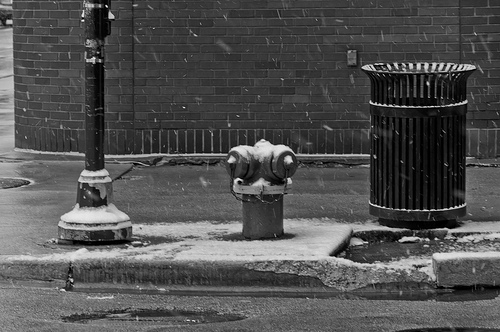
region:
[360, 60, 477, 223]
a trash can on the sidewalk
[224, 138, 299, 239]
a fire hydrant on the sidewalk near the curb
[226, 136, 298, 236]
a fire hydrant between a trash can and a pole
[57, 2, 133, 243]
a pole beside the fire hydrant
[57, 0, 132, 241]
a pole near the curb on the sidewalk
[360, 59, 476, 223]
a trash can beside a fire hydrant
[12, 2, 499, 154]
a brick wall to a building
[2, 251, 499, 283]
the curb beside the street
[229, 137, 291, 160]
snow on top of the fire hydrant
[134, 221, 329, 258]
snow on the sidewalk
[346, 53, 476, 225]
trash receptacle on the sidewalk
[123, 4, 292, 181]
bits of snow in the air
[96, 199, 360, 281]
small patch of snow on the ground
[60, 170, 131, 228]
snow on the bottom of the pole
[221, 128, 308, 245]
small fire hydrant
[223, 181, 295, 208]
chains on the fire hydrant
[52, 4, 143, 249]
pole on the sidewalk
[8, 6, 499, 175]
brick building on the corner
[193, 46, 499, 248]
trash can nearby a fire hydrant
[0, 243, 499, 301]
curb along the side of the road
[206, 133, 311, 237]
this is a fire hydrant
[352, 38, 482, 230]
thihs is a dust bin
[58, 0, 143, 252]
this is a pole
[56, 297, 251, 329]
this is a pot hole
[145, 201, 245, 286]
this is snow on the ground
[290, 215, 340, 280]
this is snow on the ground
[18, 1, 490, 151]
this is a brick wall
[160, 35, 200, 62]
bricks on the wall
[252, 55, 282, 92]
bricks on the wall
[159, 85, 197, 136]
bricks on the wall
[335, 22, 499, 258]
a trash can on the sidewalk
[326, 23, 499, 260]
a trash can that is outside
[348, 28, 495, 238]
a metal trash can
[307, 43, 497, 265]
a metal trash can on sidewalk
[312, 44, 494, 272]
a metal trash can outside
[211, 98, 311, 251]
a fire hydrant on the sidewalk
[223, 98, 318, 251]
a hydrant on the sidewalk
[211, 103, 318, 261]
snow on the fire hydrant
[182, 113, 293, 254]
snow on the hydrant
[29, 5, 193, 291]
a street pole on the sidewalk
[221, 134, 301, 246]
fire hydrant covered in snow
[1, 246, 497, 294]
curb next to the street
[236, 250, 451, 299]
damaged section of curb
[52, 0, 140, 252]
streetlight covered in snow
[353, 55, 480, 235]
metal garbage bin covered in snow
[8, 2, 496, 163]
brick wall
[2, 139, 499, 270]
wet sidewalk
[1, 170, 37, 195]
manhole cover on the sidewalk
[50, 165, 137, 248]
base of a streetlight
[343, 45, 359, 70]
small box on the brick wall